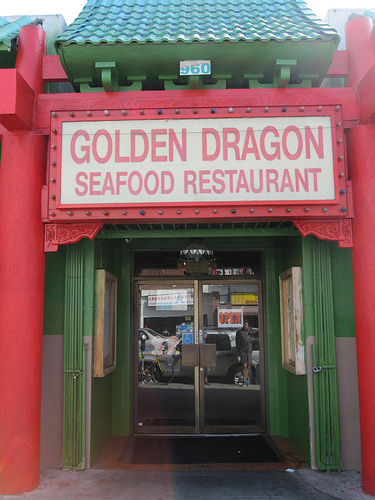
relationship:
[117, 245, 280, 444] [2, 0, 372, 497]
entrance to restaurant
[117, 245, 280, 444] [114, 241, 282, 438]
entrance has trim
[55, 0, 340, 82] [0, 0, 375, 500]
top of restaurant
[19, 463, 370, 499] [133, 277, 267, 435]
ground beneath door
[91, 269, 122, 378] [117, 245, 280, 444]
picture at entrance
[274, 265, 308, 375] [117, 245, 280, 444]
picture at entrance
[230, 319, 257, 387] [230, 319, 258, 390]
reflection of man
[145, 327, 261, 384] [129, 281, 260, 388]
car in window reflection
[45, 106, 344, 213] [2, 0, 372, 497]
sign on restaurant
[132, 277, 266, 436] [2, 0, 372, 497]
doors of restaurant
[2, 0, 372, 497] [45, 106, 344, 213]
restaurant has a sign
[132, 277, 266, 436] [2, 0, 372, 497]
doors for restaurant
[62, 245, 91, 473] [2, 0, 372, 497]
gate to close restaurant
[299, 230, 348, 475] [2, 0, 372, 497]
gate to close restaurant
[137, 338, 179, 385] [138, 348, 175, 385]
reflection of bicycle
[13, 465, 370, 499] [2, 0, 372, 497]
sidewalk leading to restaurant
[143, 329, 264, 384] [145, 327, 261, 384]
reflection of car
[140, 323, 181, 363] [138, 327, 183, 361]
reflection of car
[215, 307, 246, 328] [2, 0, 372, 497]
open sign on restaurant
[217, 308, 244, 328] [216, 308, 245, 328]
open sign says open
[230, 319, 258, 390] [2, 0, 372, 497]
man looking at restaurant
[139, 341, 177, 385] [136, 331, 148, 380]
bicycle attached to parking meter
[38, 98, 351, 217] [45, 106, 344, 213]
light bulbs surrounding sign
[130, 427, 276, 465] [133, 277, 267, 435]
door mat in front of door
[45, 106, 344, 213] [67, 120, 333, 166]
sign says golden dragon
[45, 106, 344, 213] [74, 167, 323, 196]
sign says seafood restaurant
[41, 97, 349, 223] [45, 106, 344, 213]
lights around sign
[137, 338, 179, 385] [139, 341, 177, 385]
reflection of bicycle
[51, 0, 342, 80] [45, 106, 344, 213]
awning above sign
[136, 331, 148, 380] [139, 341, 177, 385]
parking meter beside bicycle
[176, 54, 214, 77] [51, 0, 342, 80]
960 below awning